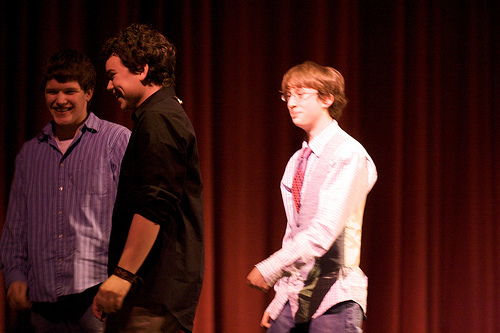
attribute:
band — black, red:
[92, 261, 177, 301]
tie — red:
[292, 144, 310, 218]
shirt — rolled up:
[116, 86, 207, 317]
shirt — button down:
[7, 112, 122, 321]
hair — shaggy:
[274, 52, 379, 129]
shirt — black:
[138, 104, 201, 220]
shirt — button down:
[9, 118, 116, 288]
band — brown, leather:
[109, 262, 144, 288]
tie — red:
[289, 150, 311, 212]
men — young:
[37, 26, 428, 315]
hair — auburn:
[281, 60, 347, 91]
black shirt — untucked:
[106, 85, 204, 332]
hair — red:
[279, 57, 344, 117]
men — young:
[2, 17, 378, 331]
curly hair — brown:
[102, 23, 177, 83]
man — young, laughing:
[97, 20, 207, 331]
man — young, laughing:
[0, 47, 131, 331]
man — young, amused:
[245, 59, 378, 331]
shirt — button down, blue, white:
[0, 110, 130, 304]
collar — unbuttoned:
[35, 110, 103, 153]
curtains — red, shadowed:
[0, 0, 499, 331]